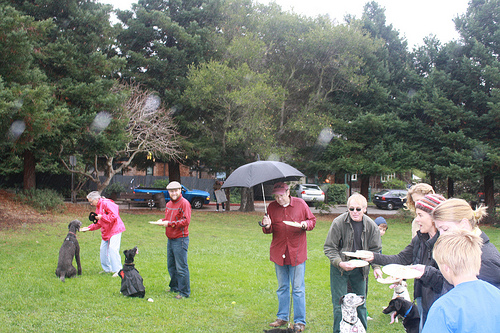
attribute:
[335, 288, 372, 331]
dog — white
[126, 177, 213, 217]
truck — blue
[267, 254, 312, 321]
jeans — BLUE 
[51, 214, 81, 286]
dog — sitting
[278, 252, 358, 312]
jeans — blue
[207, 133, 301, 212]
umbrella — black